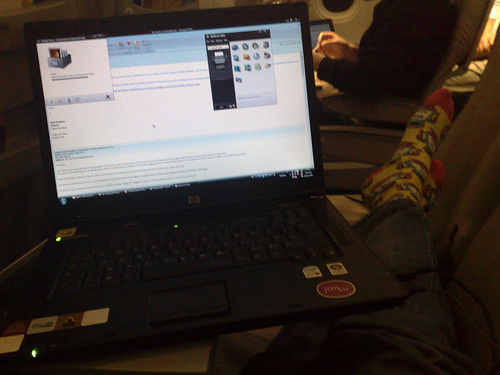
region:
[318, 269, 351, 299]
logo is on the laptop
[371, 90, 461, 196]
the socks are red and yellow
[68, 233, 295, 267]
the keyboard letters are black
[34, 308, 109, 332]
sticker is on the laptop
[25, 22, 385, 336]
the laptop is on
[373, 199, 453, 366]
the jeans are blue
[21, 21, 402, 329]
the laptop is a hp model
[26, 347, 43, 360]
the light is blue in color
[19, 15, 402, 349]
a black laptop next to a person's leg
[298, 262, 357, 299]
stickers on a laptop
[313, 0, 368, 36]
a round window on a plane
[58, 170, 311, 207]
the task bar at the bottom of the screen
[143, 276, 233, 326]
a mousepad on the laptop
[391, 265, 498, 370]
cords connected to a laptop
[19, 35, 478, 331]
a laptop on a couch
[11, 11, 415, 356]
the laptop is on the person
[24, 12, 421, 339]
the laptop is touching someone's leg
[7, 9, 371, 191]
a screen on the laptop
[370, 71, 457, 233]
colorful socks on the person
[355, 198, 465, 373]
the person is wearing jeans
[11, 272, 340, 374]
stickers on the laptop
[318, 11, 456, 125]
a person on in a seat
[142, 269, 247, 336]
a track wheel on a laptop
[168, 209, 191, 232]
a green light on the laptop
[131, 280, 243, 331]
Mouse pad on a laptop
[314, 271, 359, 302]
sticker on a laptop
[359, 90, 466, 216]
Socks on feet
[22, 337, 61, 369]
Green light on a laptop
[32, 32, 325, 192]
Screen on a laptop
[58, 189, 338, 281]
Keys on a laptop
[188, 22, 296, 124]
Window on a screen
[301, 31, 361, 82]
Hands on a person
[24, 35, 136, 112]
White window on a laptop screen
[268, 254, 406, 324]
Stickers on a laptop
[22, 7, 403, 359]
a black laptop computer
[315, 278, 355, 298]
a red and white sticker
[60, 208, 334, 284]
keyboard of a laptop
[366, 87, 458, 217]
red and green socks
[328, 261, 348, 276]
windows sticker on a computer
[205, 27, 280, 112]
window open on a screen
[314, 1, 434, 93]
arm of a person who is sitting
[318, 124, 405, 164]
an armrest on a seat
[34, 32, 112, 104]
window open on a screen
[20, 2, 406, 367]
open black laptop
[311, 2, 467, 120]
person using laptop on airplane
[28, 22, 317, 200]
powered up laptop screen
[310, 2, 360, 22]
round airplane window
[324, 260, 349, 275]
windows sticker on a laptop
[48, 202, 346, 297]
black laptop keyboard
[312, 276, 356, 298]
oval red sticker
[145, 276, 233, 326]
mouse pad on a laptop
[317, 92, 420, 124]
airplane seat arm rest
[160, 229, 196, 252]
a button on the keyboard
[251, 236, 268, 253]
a button on the keyboard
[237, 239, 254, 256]
a button on the keyboard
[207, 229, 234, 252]
a button on the keyboard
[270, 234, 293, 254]
a button on the keyboard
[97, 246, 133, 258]
a button on the keyboard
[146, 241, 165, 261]
a button on the keyboard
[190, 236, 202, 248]
a button on the keyboard